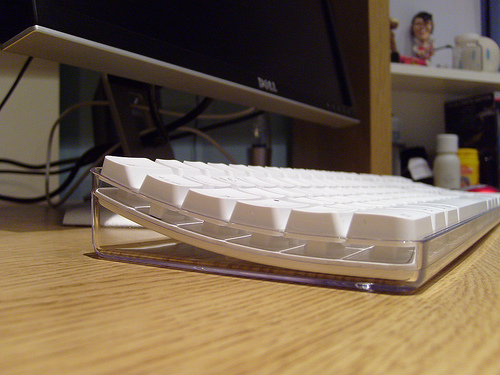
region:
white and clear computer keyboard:
[91, 154, 499, 291]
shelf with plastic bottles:
[391, 76, 499, 191]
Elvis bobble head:
[411, 11, 452, 65]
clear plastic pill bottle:
[456, 34, 481, 69]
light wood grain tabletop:
[0, 201, 497, 374]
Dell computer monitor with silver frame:
[0, 0, 362, 128]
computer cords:
[0, 55, 274, 204]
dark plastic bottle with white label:
[399, 147, 432, 183]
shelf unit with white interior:
[288, 0, 498, 186]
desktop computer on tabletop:
[0, 0, 498, 374]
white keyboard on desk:
[91, 149, 498, 297]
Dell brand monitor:
[7, 9, 365, 128]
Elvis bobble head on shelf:
[407, 7, 454, 72]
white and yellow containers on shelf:
[430, 127, 483, 192]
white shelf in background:
[387, 56, 498, 97]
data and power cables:
[7, 58, 289, 193]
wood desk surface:
[7, 210, 497, 370]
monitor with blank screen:
[15, 1, 359, 126]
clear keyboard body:
[84, 174, 498, 285]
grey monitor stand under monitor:
[72, 78, 204, 245]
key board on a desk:
[85, 159, 491, 287]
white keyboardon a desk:
[137, 169, 472, 274]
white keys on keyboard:
[284, 168, 438, 223]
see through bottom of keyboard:
[80, 182, 137, 259]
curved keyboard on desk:
[77, 119, 457, 280]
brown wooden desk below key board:
[7, 259, 167, 374]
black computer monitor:
[52, 0, 371, 129]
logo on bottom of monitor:
[252, 73, 276, 95]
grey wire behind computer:
[29, 100, 86, 148]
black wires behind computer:
[0, 149, 40, 196]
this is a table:
[53, 290, 138, 326]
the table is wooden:
[57, 288, 176, 344]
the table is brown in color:
[71, 287, 238, 348]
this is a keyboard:
[92, 139, 481, 251]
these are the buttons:
[243, 188, 319, 213]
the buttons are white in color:
[286, 187, 366, 222]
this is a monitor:
[12, 7, 389, 112]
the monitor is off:
[217, 6, 283, 34]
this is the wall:
[442, 8, 461, 21]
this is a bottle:
[432, 134, 465, 184]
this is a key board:
[269, 158, 409, 236]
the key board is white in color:
[285, 167, 374, 228]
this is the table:
[231, 296, 336, 368]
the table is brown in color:
[242, 287, 299, 344]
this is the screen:
[226, 7, 321, 78]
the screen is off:
[254, 13, 318, 69]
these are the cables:
[50, 88, 197, 143]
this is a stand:
[83, 200, 137, 259]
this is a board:
[366, 43, 391, 74]